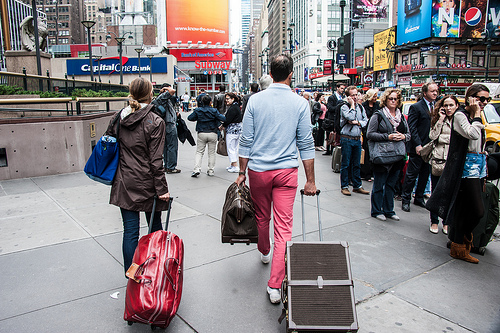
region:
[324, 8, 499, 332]
several people standing on a busy street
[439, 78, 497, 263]
two women talking on their cellphones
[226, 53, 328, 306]
a man wearing pink pants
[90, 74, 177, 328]
a woman pulling a red suitcase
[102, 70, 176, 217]
a woman wearing a brown jacket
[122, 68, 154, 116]
a woman with blonde hair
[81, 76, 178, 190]
a woman carrying a blue bag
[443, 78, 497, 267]
a woman wearing brown boots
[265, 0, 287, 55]
the facade of a building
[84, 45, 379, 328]
two people pulling suitcases behind them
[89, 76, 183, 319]
the woman's suitcase is red in color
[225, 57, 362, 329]
the mans suitcase is brown in color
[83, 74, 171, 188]
the woman carries a small blue bag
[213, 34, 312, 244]
the man carries a large leather bag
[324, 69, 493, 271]
many people are at a stand still on the sidewalk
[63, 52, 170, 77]
a bank's advertisement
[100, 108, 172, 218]
the woman wears a jacket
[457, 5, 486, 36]
a PEPSI logo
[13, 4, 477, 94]
several buildings are in the background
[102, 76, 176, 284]
Woman wearing a brown jacket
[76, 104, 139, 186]
Blue bag on woman's shoulder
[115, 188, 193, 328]
Red luggage behind the woman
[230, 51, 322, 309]
Man wearing pink pants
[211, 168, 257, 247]
Bag in man's hand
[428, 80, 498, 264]
Woman wearing blue jean shorts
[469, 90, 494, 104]
Glasses on woman's face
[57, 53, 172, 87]
Blue sign on building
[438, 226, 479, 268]
Brown boots on woman's feet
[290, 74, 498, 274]
Crowd of people on sidewalk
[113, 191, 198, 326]
red suit case rolling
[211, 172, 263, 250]
brown suit case in hand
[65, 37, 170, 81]
capital one bank sign on side of wall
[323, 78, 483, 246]
several people in a line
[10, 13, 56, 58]
large bird statue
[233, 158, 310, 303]
pink men's pants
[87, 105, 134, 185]
blue bag on shoulder of lady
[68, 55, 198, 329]
lady walking on sidewalk with suitcase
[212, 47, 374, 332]
man walking down sidewalk with suitcase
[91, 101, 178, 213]
brown coat on lady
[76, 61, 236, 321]
woman pulling a suitcase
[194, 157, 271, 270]
the bag is brown